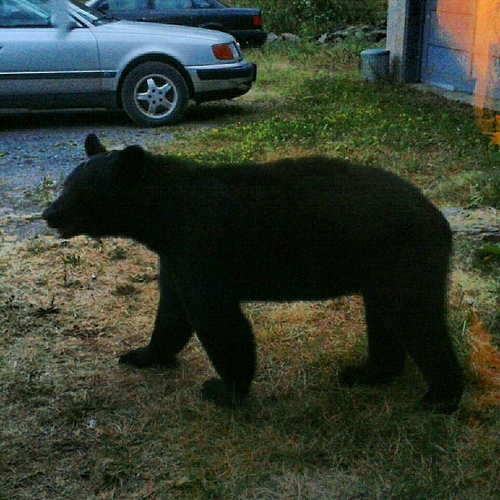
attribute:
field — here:
[3, 6, 499, 492]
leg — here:
[189, 300, 257, 401]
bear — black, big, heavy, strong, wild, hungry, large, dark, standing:
[40, 133, 463, 418]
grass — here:
[162, 7, 498, 479]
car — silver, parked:
[1, 0, 259, 126]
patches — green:
[3, 167, 499, 498]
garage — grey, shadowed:
[380, 3, 498, 108]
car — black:
[86, 1, 271, 49]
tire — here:
[117, 59, 187, 124]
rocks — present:
[265, 28, 378, 51]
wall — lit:
[384, 3, 499, 114]